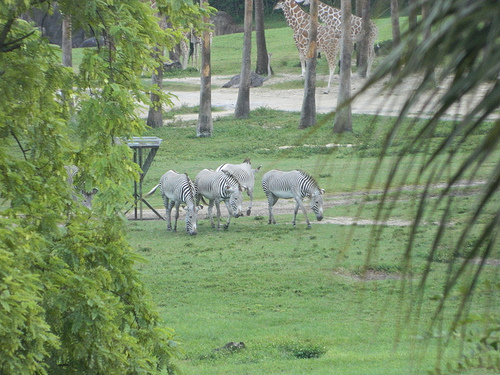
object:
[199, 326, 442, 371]
grass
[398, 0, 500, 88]
leaf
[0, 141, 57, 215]
leaf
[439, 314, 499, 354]
leaf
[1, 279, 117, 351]
leaf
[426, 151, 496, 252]
leaf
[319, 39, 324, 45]
spot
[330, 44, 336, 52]
spot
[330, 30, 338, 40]
spot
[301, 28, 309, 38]
spot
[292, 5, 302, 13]
spot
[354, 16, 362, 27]
spot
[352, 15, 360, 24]
spot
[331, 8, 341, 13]
spot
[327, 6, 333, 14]
spot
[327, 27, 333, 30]
spot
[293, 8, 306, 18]
spot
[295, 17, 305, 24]
spot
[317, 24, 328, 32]
spot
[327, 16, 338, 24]
spot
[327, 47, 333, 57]
spot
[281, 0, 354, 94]
giraffe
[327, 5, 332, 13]
spot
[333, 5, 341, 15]
spot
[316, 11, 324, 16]
spot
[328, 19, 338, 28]
spot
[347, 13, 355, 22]
spot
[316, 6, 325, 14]
spot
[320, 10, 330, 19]
spot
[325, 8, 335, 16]
spot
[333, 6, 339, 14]
spot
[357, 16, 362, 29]
spot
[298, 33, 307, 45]
spot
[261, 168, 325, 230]
zebra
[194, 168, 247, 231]
zebra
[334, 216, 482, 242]
grass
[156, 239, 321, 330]
area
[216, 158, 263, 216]
zebra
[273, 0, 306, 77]
giraffe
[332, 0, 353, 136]
tree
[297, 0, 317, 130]
tree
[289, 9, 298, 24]
spot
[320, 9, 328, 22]
spot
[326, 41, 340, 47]
spot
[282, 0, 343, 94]
giraffe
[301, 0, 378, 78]
giraffe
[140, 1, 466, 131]
background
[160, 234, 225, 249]
grass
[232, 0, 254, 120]
tree trunk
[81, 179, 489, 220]
path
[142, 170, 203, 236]
zebra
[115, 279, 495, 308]
grass